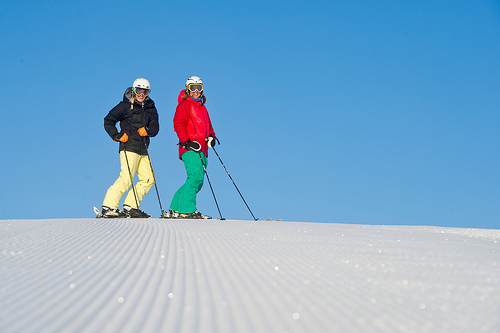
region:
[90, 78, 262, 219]
two skiers on top of a slope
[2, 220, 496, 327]
a snowy ski slope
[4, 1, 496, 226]
clear blue sky above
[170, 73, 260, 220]
skier with the green pants and red jacket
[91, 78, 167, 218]
skier with the black jacket and yellow pants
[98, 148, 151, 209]
yellow ski pants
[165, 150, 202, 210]
green ski pants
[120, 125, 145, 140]
orange gloves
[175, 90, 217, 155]
red ski jacket on right skier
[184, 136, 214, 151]
black and white ski gloves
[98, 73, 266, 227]
two people snow skiing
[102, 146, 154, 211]
tan snow ski pants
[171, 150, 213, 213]
teal snow ski pants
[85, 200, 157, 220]
black and grey skiies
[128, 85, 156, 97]
teal snow ski goggles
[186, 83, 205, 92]
white snow ski goggles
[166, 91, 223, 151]
red snow ski jacket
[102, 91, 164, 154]
black snow ski jacket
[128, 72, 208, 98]
couple wearing white helmets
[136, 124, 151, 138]
orange snow ski gloves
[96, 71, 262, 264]
two people skiing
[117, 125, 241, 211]
people holding ski poles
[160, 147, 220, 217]
pants are green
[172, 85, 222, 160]
jacket is red and black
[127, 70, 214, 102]
helmets are white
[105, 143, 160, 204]
the pants are yellow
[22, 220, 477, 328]
snowy hill is very flat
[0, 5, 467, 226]
clear blue sky behind skiers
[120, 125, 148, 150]
person is wearing orange gloves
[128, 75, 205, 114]
two people are smiling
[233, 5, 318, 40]
this is the sky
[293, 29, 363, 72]
the sky is blue in color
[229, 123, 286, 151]
the sky has clouds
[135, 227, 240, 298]
this is the ground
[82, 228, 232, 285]
the ground has snow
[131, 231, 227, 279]
the snow is white in color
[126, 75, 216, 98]
these are two helmets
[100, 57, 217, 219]
these are two people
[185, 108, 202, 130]
the jacket is red in color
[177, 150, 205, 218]
teal pants on a skier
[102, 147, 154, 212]
cream pants on a skier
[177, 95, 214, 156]
red jacket on a skier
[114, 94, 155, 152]
black jacket on skier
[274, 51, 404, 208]
clear blue sky without any clouds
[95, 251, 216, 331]
paralell lines on a ski slope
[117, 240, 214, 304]
rake linesi n the snow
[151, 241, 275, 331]
snow on the ski slope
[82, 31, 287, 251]
two skiers side by side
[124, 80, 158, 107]
white helmet on a skier's head